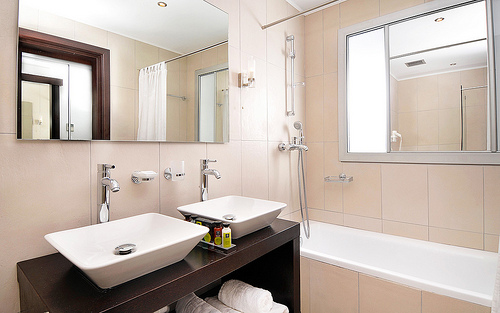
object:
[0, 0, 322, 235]
wall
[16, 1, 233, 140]
mirror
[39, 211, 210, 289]
color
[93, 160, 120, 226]
tap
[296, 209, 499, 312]
tub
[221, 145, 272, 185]
tile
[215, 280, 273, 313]
towels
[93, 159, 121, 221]
faucets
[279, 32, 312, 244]
shower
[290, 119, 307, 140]
head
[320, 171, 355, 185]
grab bar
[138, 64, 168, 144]
shower curtain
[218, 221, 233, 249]
toiletries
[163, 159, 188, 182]
cup holder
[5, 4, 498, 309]
room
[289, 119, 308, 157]
shower sprayer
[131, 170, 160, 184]
soap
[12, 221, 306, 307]
vanity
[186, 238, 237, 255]
tray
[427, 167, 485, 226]
tiles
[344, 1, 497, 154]
mirror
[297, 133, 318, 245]
tubing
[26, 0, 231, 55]
ceiling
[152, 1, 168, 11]
light fixture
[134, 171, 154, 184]
dish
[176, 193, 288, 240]
sink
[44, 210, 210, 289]
sink